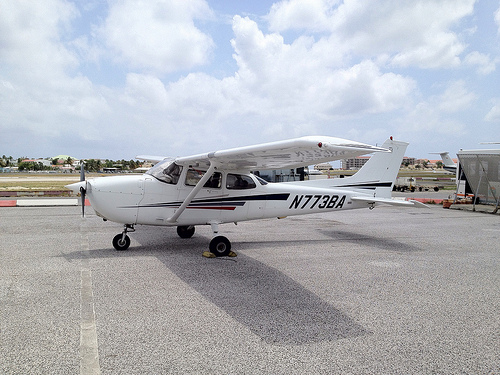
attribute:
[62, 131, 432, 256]
plane — small, white, parked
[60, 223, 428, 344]
shadow — dark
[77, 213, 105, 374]
line — white, dirty white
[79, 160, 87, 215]
propeller — black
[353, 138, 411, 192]
tail — white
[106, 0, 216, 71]
cloud — white, fluffy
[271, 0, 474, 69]
cloud — white, fluffy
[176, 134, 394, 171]
wing — long, wihte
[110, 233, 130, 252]
tire — deployed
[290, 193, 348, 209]
writing — black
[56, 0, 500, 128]
sky — blue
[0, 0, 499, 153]
clouds — white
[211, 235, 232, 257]
tire — blocked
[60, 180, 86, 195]
nosecone — white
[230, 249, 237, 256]
chock — wooden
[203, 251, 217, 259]
chock — wooden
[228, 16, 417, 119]
cloud — white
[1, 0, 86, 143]
cloud — white